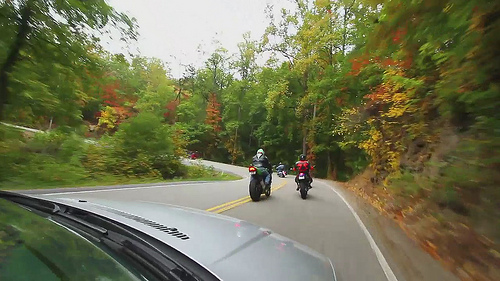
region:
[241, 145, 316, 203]
Motorcycles driving on a road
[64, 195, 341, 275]
Hood of gray car on road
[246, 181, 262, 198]
Back tire of motorcycle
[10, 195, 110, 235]
Black windshield wiper on car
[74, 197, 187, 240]
Long thin grill on car hood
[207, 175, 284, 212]
Double yellow line on road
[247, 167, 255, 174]
Red tail light on motorcycle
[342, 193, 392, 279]
White line on side of road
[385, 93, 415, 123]
Yellow autumn leaves on tree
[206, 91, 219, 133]
Orange autumn leaves on tree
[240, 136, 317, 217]
bikers going down a curved road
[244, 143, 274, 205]
guy on a motor bike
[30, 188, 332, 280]
hood of a silver vehicle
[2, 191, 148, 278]
wind shield of a vehicle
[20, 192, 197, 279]
windshield wipers on a vehicle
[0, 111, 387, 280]
a curvy road in a forest area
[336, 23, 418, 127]
leaves on the trees about to change colors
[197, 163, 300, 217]
yellow lines painted on the road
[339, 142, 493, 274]
objects are blurry because of motion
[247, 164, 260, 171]
back headlight on the motorbike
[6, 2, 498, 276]
Trees with leaves that are changing color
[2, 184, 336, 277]
Hood and windshield of silver car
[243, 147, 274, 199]
Man in black jacket riding motorcycle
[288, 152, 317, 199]
Man in red and black jacket riding motorcycle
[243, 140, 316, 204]
Three people riding motorcycles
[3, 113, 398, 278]
Road curving to the left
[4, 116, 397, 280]
Car following three motorcycles down road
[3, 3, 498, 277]
Trees lining both sides of road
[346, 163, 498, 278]
Brown ground littered with yellow leaves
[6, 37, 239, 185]
Group of trees and bushes to left of road